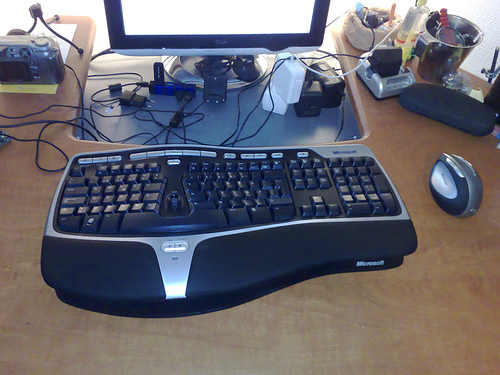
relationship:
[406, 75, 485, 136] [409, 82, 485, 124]
case for eye glasses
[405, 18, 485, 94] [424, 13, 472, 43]
cup with supplies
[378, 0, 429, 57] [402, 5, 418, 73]
ink in case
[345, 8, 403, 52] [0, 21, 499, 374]
bowl in backoff desk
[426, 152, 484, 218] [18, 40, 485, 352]
mouse on table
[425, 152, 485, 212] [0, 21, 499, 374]
mouse on desk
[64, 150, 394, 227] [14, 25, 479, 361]
keyboard on desk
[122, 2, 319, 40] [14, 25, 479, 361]
monitor on desk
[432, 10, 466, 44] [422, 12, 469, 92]
trinkets in cup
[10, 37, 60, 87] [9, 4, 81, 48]
camera with tripod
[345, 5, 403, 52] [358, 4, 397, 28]
bowl of items